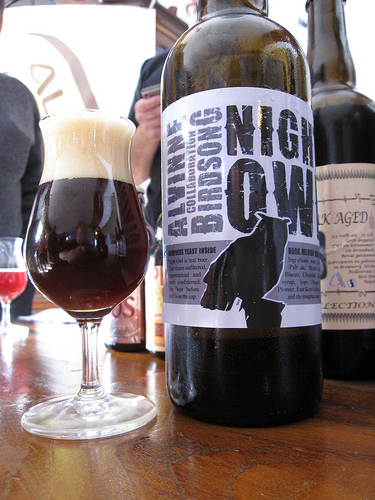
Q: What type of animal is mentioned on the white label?
A: Night Owl.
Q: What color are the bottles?
A: Brown.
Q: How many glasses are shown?
A: Two.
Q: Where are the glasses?
A: On the table.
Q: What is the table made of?
A: Wood.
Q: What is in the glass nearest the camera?
A: Beer.